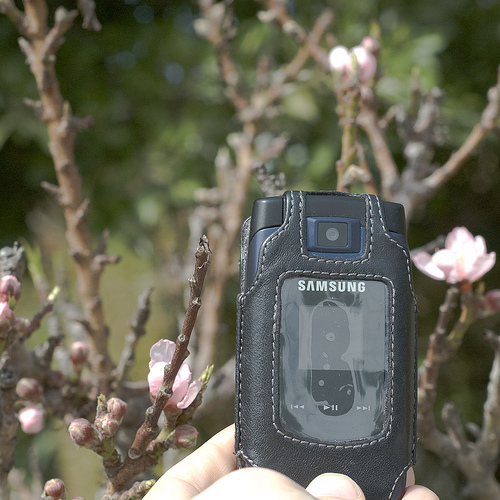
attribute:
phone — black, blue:
[216, 167, 441, 499]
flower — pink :
[411, 225, 496, 285]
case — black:
[268, 194, 410, 497]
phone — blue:
[250, 198, 407, 495]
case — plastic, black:
[229, 183, 423, 498]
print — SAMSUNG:
[296, 279, 366, 293]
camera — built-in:
[303, 212, 360, 259]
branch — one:
[68, 235, 218, 499]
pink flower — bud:
[142, 337, 204, 407]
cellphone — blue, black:
[253, 195, 419, 295]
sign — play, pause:
[310, 385, 341, 420]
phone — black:
[222, 181, 425, 498]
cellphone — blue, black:
[249, 194, 419, 460]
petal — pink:
[463, 249, 498, 281]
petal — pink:
[474, 234, 484, 260]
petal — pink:
[432, 248, 460, 279]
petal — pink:
[407, 249, 439, 276]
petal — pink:
[447, 225, 470, 251]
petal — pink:
[144, 329, 199, 415]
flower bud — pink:
[383, 187, 498, 302]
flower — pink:
[147, 335, 202, 405]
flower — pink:
[142, 340, 199, 410]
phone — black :
[234, 186, 419, 483]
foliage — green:
[68, 26, 199, 220]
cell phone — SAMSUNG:
[240, 185, 422, 497]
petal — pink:
[146, 339, 210, 411]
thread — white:
[249, 248, 421, 474]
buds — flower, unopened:
[59, 395, 136, 447]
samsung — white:
[288, 247, 438, 309]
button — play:
[321, 398, 348, 416]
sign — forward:
[355, 401, 371, 414]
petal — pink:
[329, 45, 356, 87]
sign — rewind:
[287, 399, 308, 414]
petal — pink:
[177, 381, 199, 411]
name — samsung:
[295, 275, 370, 294]